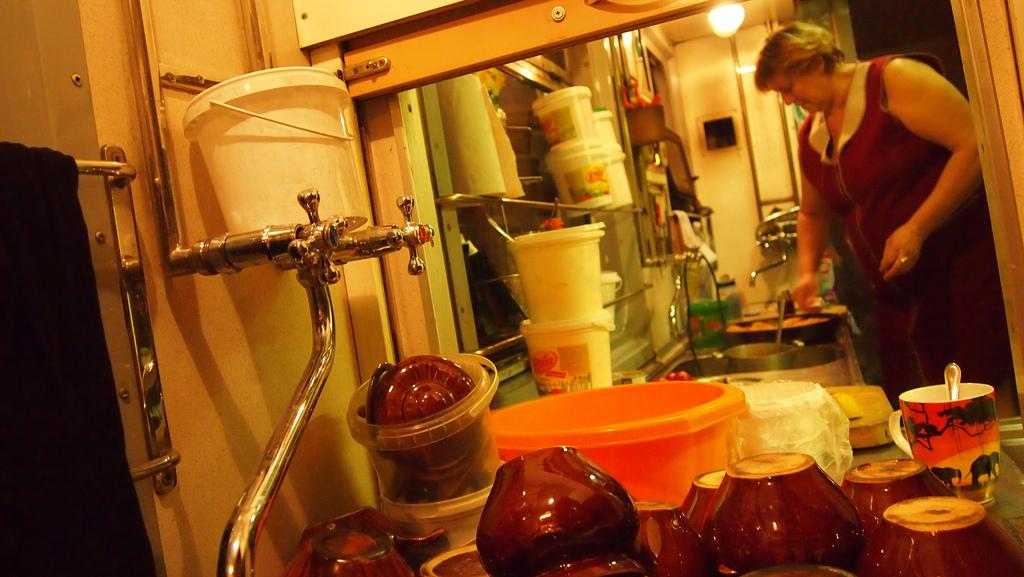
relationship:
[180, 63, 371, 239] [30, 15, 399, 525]
bucket on wall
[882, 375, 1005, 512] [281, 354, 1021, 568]
mug on table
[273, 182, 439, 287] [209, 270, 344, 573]
faucet knob on pipe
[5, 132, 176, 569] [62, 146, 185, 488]
towel hanging on rack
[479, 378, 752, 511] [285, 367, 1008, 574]
plastic bowl on table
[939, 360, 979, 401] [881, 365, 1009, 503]
spoon in mug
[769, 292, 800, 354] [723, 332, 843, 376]
utensil in pot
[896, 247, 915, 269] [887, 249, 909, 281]
ring on finger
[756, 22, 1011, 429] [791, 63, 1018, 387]
woman wearing dress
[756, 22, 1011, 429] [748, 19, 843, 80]
woman has hair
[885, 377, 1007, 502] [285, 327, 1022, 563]
coffee mug on counter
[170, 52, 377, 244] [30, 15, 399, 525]
bucket next to wall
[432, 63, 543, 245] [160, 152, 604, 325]
paper towel on shelf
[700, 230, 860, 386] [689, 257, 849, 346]
food in frying pan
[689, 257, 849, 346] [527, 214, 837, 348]
frying pan on counter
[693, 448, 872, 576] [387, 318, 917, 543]
cup on table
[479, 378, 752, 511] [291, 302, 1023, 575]
plastic bowl on counter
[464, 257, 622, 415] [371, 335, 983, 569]
object on table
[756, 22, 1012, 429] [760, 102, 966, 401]
woman wearing dress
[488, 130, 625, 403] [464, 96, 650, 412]
set of buckets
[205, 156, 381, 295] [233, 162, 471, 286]
set of knobs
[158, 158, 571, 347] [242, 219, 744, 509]
set of dishes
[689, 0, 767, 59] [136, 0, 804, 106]
light on ceiling